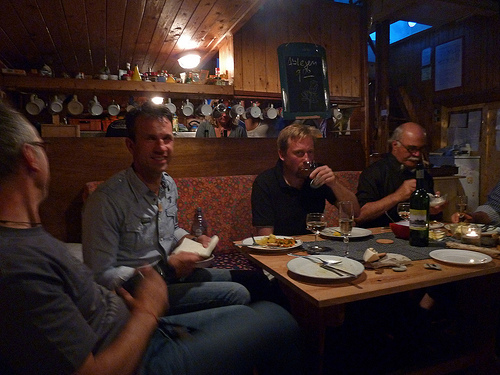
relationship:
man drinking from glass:
[251, 124, 359, 234] [298, 159, 324, 188]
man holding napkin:
[82, 102, 268, 300] [174, 234, 219, 257]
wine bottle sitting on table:
[409, 164, 432, 245] [230, 219, 500, 374]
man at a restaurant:
[82, 102, 268, 300] [2, 0, 500, 374]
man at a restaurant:
[251, 124, 359, 234] [2, 0, 500, 374]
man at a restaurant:
[355, 122, 449, 220] [2, 0, 500, 374]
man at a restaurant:
[0, 95, 306, 374] [2, 0, 500, 374]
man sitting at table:
[0, 95, 306, 374] [230, 219, 500, 374]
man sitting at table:
[251, 124, 359, 234] [230, 219, 500, 374]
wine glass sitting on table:
[306, 212, 327, 252] [230, 219, 500, 374]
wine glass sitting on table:
[397, 200, 411, 222] [230, 219, 500, 374]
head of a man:
[122, 101, 174, 171] [82, 102, 268, 300]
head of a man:
[390, 123, 428, 166] [355, 122, 449, 220]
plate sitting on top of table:
[287, 254, 363, 279] [230, 219, 500, 374]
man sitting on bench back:
[251, 124, 359, 234] [83, 169, 363, 252]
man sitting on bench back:
[355, 122, 449, 220] [83, 169, 363, 252]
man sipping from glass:
[251, 124, 359, 234] [298, 159, 324, 188]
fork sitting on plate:
[290, 247, 342, 268] [287, 254, 363, 279]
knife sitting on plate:
[317, 260, 356, 278] [287, 254, 363, 279]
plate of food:
[239, 232, 304, 250] [258, 232, 297, 248]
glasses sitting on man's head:
[398, 138, 428, 153] [390, 123, 428, 166]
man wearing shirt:
[82, 102, 268, 300] [80, 163, 187, 279]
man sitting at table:
[355, 122, 449, 220] [230, 219, 500, 374]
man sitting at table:
[82, 102, 268, 300] [230, 219, 500, 374]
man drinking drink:
[251, 124, 359, 234] [297, 164, 312, 176]